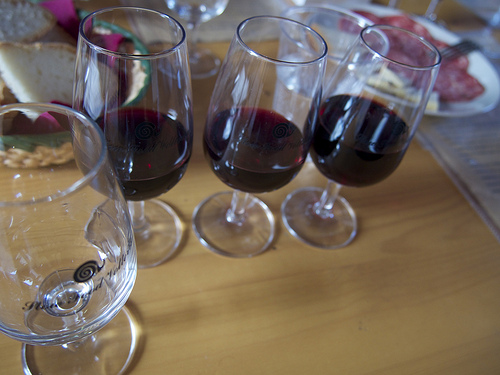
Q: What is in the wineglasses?
A: Wine.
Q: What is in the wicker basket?
A: Bread.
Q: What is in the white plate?
A: Food.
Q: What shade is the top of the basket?
A: Green.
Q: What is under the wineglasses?
A: Table.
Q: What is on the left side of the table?
A: An empty wine glass.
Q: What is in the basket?
A: Bread.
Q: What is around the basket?
A: Green trim.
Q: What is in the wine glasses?
A: Burgundy wine.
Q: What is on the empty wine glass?
A: A logo and text.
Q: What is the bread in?
A: A basket.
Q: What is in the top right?
A: A plate.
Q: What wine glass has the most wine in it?
A: The one on the right.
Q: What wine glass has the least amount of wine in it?
A: The middle glass.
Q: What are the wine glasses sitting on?
A: A light brown wood table.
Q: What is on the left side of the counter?
A: An empty wine glass.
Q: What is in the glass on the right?
A: Red wine.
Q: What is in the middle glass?
A: Red liquid.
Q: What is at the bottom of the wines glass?
A: Stem.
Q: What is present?
A: Glasses.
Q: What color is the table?
A: Brown.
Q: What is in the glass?
A: Wine.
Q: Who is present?
A: Nobody.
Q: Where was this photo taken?
A: At a restaurant.